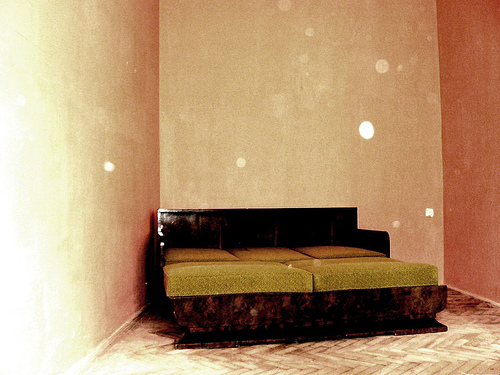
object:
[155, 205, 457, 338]
bed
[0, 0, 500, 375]
room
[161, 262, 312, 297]
cushion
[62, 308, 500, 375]
floor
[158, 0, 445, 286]
wall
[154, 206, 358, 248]
headboard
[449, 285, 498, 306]
molding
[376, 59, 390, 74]
spot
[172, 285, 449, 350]
foot board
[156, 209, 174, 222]
light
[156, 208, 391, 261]
wood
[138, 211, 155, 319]
shadow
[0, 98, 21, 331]
light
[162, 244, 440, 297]
mattress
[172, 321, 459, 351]
carpet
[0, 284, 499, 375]
ground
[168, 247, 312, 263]
pillows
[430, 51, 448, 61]
corner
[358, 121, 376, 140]
orb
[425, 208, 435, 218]
square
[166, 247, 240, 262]
pillow